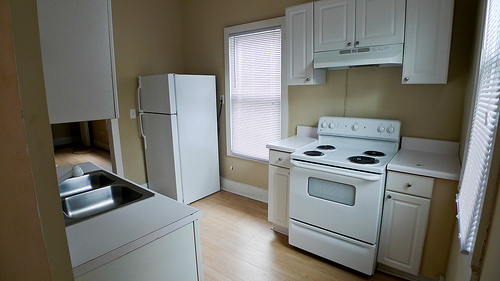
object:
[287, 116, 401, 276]
stove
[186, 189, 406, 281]
floor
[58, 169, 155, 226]
sink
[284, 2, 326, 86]
cabinet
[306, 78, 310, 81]
knob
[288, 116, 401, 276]
oven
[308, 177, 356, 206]
window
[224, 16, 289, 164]
blinds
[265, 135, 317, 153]
counter top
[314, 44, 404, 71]
hood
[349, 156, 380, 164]
burner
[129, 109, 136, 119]
light switch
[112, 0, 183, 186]
wall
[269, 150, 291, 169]
kitchen drawer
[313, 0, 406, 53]
cabinet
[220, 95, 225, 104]
outlet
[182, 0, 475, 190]
wall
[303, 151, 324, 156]
burner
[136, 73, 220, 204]
freezer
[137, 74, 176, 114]
door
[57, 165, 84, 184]
faucet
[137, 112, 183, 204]
door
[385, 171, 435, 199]
kitchen drawer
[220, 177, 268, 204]
trim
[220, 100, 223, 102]
refridgerator plug